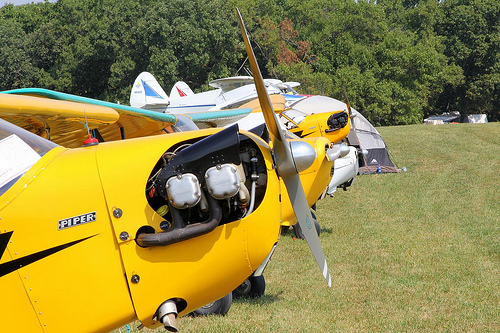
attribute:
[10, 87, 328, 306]
yellow plane — small 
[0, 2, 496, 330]
picture — taken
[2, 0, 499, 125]
trees — green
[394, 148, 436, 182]
ground — grassy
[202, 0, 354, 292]
propeller — metal, shiny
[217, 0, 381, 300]
propeller — gray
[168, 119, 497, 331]
grass — short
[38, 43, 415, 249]
propeller — upright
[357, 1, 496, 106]
trees — thick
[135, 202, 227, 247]
tubing — black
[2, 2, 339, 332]
airplane — lined up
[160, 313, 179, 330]
pipe — small, exhaust pipe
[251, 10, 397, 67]
tree — dry, greeb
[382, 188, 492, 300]
grass — brown, green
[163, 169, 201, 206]
box — metal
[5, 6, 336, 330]
plane — yellow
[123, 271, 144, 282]
screw — small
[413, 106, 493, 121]
buildings — small